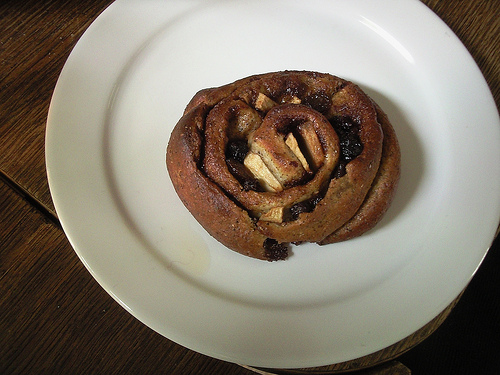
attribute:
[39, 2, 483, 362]
plate — white, round, clean, one, plain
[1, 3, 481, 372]
table — brown, wood, dark brown, wooden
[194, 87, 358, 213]
swirls — many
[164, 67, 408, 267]
cinnamon roll — brown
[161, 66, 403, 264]
breakfast pastry — brown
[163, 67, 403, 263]
pastry — round, raisin filled, sweet, cooked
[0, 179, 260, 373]
section — small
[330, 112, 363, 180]
filling — gooey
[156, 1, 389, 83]
section — small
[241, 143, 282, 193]
filling — gooey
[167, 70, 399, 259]
cinnamon roll — raisin filled